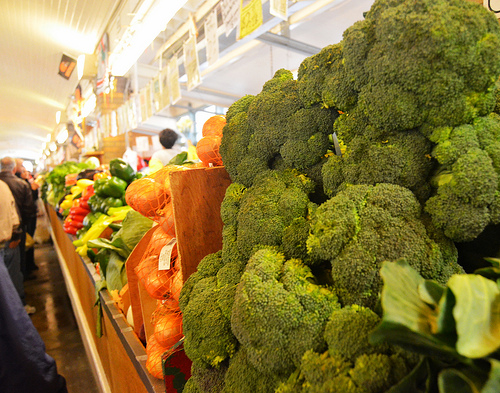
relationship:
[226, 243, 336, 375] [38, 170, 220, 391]
broccoli in stand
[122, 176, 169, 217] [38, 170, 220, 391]
onion in stand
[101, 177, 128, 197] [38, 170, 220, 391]
pepper in stand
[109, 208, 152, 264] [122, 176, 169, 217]
lettuce by onion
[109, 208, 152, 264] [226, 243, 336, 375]
lettuce by broccoli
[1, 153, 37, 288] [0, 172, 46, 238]
man in jacket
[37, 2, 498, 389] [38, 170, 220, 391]
produce in stand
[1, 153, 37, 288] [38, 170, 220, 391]
man by stand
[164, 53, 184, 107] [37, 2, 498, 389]
sign over produce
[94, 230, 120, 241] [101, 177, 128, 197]
carrot by pepper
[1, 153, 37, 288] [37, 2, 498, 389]
man by produce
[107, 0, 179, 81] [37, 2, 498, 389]
light above produce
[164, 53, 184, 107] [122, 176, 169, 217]
sign above onion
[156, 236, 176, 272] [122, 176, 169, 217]
label on onion